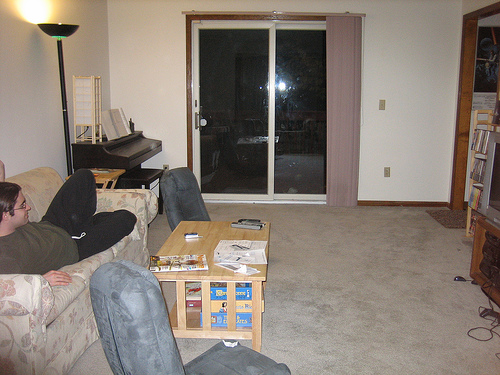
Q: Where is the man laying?
A: On couch.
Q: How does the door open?
A: By sliding.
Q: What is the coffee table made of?
A: Wood.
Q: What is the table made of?
A: Wood.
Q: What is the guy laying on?
A: Couch.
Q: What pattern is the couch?
A: Flowers.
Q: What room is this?
A: Living room.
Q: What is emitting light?
A: Lamp.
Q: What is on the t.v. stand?
A: Television.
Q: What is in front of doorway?
A: Rug.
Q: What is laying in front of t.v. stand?
A: Controller.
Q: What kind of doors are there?
A: Sliding glass.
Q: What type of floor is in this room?
A: Beige carpet.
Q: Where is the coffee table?
A: In front of the couch.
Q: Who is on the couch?
A: A man with glasses.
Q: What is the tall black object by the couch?
A: A floor lamp.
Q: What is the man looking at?
A: The television.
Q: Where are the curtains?
A: To the right in front of the sliding glass doors.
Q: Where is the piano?
A: To the right of the floor lamp.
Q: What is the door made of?
A: Glass and metal.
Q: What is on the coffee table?
A: Magazines.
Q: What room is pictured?
A: Living Room.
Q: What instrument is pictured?
A: Piano.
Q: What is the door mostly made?
A: Glass.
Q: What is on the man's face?
A: Glasses.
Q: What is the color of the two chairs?
A: Gray.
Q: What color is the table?
A: Brown.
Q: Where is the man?
A: On the couch.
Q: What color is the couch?
A: Cream.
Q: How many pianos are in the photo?
A: 1.